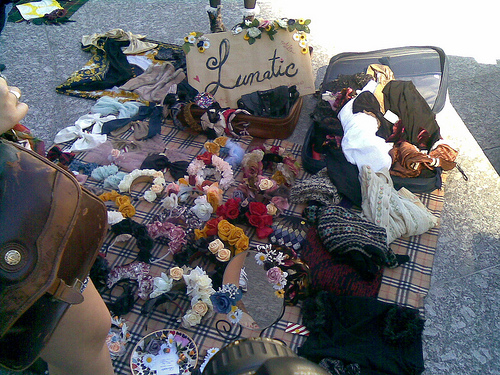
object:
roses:
[217, 220, 235, 241]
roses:
[226, 205, 239, 219]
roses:
[167, 238, 185, 254]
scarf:
[388, 141, 459, 178]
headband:
[241, 144, 299, 194]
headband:
[187, 152, 234, 193]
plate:
[130, 329, 199, 375]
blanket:
[45, 117, 442, 375]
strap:
[46, 277, 84, 304]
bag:
[0, 138, 108, 375]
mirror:
[222, 250, 285, 340]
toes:
[255, 325, 258, 327]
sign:
[203, 38, 298, 98]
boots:
[206, 5, 226, 34]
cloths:
[337, 79, 393, 173]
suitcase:
[300, 45, 448, 193]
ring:
[10, 90, 20, 98]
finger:
[9, 86, 21, 106]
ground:
[2, 22, 95, 146]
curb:
[445, 88, 498, 194]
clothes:
[317, 206, 410, 280]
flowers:
[192, 300, 207, 316]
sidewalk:
[80, 0, 205, 30]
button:
[0, 237, 38, 282]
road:
[460, 41, 498, 120]